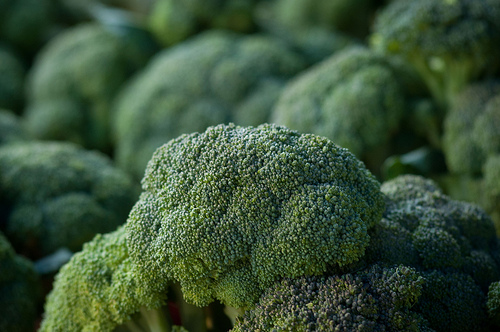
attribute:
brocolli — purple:
[43, 121, 499, 330]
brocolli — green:
[128, 115, 435, 311]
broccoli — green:
[128, 120, 388, 330]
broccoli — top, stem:
[263, 44, 439, 136]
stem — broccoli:
[276, 220, 383, 292]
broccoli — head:
[29, 120, 486, 330]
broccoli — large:
[140, 108, 376, 306]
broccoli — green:
[10, 5, 460, 270]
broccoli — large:
[135, 116, 385, 288]